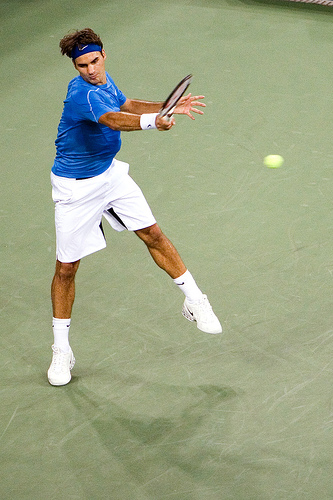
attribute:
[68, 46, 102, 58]
band — blue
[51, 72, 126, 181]
shirt — blue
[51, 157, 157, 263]
shorts — white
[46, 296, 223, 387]
shoe — white, bright, black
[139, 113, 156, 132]
wrist band — white, thick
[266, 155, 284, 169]
ball — small, yellow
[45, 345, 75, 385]
shoe — white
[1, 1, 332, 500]
surface — green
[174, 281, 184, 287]
logo — black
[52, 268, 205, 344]
socks — white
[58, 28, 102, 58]
hair — brown, floppy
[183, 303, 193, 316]
check — black